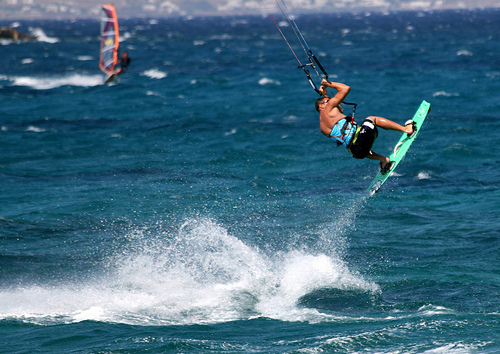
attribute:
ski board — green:
[363, 98, 431, 198]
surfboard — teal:
[361, 98, 431, 201]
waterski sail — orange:
[94, 5, 124, 82]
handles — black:
[271, 52, 376, 109]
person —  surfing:
[309, 77, 415, 169]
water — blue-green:
[2, 12, 498, 345]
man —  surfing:
[308, 79, 415, 175]